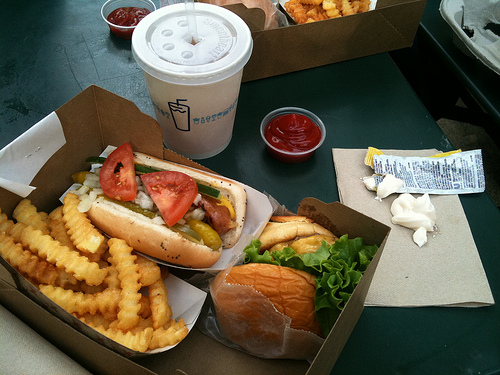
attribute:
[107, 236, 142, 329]
fry — french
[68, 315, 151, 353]
fry — french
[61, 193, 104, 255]
fry — french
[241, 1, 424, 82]
box — cardboard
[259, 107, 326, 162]
cup — plastic, one serving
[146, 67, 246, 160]
cup — white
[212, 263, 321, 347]
bun — bread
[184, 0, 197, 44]
straw — clear, plastic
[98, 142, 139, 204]
tomato — sliced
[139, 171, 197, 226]
tomato — sliced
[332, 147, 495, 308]
napkin — paper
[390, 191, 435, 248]
mayo — foil packed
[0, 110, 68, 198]
receipt — stapled, white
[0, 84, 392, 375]
box — another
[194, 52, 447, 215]
table — green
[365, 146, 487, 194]
mayonaisse — packet